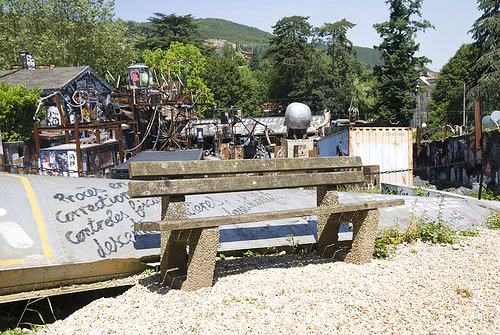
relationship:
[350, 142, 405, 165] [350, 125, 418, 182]
paint on wall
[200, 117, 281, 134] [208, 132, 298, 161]
roof of a house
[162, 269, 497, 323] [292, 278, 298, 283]
ground has gravel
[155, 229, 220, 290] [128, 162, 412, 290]
leg of bench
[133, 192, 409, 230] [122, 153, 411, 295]
seat of bench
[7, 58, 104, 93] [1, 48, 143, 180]
roof of house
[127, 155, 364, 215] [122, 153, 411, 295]
backrest of bench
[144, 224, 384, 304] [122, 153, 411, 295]
shadow of bench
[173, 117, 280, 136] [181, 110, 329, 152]
roof of house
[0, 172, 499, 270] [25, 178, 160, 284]
paint on wall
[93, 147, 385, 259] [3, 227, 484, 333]
bench on ground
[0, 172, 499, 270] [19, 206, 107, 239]
paint on wall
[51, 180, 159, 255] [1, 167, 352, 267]
writing on ground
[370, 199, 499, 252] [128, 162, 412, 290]
weeds are by bench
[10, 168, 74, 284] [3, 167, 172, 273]
line on sidewalk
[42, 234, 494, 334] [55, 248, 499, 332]
pebbles are on ground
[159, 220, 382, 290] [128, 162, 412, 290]
legs are on bench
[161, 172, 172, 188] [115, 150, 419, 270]
bolts are on bench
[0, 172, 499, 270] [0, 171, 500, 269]
paint on wall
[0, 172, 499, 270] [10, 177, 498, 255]
paint on wall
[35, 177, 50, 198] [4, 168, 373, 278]
gray paint on wall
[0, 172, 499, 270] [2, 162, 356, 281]
paint on wall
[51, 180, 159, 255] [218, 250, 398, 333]
writing on ground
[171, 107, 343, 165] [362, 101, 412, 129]
building on ground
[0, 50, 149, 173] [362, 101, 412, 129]
building on ground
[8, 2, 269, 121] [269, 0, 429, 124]
tree lines in tree lines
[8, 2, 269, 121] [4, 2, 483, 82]
tree lines in background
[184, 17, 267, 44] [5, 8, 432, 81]
mountain line in background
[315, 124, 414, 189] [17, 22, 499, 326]
container in background